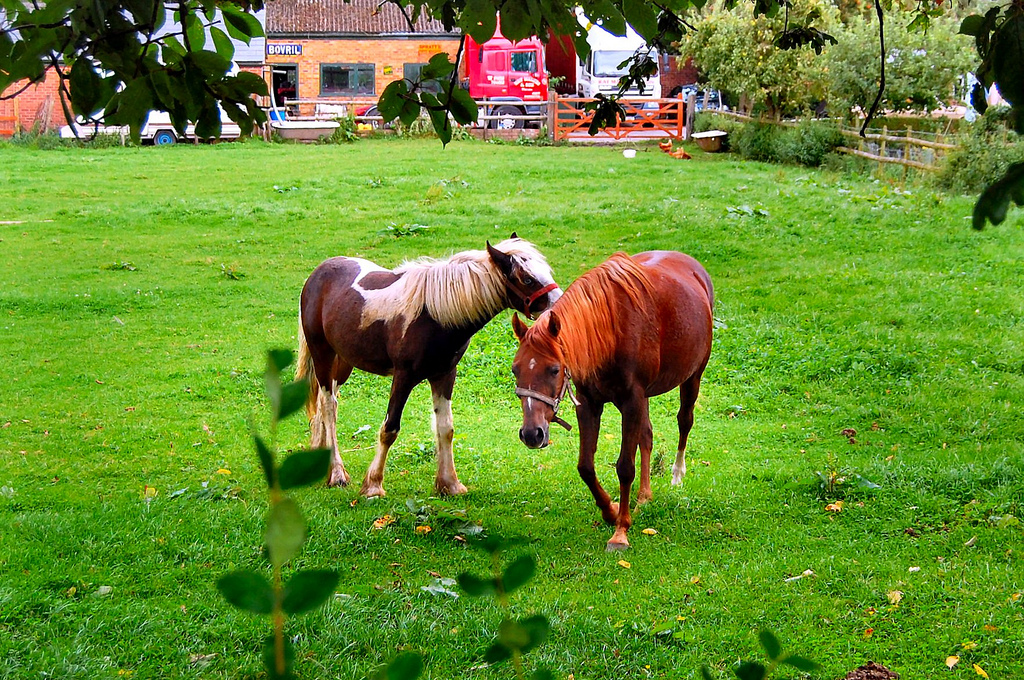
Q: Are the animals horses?
A: Yes, all the animals are horses.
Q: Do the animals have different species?
A: No, all the animals are horses.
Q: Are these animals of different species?
A: No, all the animals are horses.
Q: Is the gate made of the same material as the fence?
A: Yes, both the gate and the fence are made of wood.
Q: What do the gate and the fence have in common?
A: The material, both the gate and the fence are wooden.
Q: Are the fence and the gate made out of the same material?
A: Yes, both the fence and the gate are made of wood.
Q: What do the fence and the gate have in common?
A: The material, both the fence and the gate are wooden.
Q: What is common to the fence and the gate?
A: The material, both the fence and the gate are wooden.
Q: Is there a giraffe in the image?
A: No, there are no giraffes.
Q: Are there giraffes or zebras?
A: No, there are no giraffes or zebras.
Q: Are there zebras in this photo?
A: No, there are no zebras.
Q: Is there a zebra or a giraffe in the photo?
A: No, there are no zebras or giraffes.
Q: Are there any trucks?
A: Yes, there is a truck.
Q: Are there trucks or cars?
A: Yes, there is a truck.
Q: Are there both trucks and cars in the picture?
A: No, there is a truck but no cars.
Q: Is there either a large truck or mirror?
A: Yes, there is a large truck.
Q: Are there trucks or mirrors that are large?
A: Yes, the truck is large.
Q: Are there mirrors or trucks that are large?
A: Yes, the truck is large.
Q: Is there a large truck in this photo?
A: Yes, there is a large truck.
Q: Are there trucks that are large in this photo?
A: Yes, there is a large truck.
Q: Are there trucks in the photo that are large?
A: Yes, there is a truck that is large.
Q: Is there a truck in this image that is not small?
A: Yes, there is a large truck.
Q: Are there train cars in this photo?
A: No, there are no train cars.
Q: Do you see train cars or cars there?
A: No, there are no train cars or cars.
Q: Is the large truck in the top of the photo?
A: Yes, the truck is in the top of the image.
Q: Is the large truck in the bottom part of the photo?
A: No, the truck is in the top of the image.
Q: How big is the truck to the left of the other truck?
A: The truck is large.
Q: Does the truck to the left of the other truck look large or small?
A: The truck is large.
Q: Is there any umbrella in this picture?
A: No, there are no umbrellas.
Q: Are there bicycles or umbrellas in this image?
A: No, there are no umbrellas or bicycles.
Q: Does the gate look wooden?
A: Yes, the gate is wooden.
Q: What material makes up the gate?
A: The gate is made of wood.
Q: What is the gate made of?
A: The gate is made of wood.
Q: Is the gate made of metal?
A: No, the gate is made of wood.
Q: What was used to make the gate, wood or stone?
A: The gate is made of wood.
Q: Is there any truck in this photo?
A: Yes, there is a truck.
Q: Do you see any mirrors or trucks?
A: Yes, there is a truck.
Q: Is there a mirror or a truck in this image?
A: Yes, there is a truck.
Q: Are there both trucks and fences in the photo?
A: Yes, there are both a truck and a fence.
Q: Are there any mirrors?
A: No, there are no mirrors.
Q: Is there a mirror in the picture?
A: No, there are no mirrors.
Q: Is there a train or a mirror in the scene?
A: No, there are no mirrors or trains.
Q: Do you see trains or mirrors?
A: No, there are no mirrors or trains.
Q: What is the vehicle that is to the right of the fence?
A: The vehicle is a truck.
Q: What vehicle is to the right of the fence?
A: The vehicle is a truck.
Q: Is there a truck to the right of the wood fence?
A: Yes, there is a truck to the right of the fence.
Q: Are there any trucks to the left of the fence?
A: No, the truck is to the right of the fence.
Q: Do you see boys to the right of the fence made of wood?
A: No, there is a truck to the right of the fence.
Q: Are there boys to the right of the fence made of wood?
A: No, there is a truck to the right of the fence.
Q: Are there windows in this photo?
A: Yes, there is a window.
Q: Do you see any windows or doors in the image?
A: Yes, there is a window.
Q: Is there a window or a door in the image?
A: Yes, there is a window.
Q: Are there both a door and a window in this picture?
A: Yes, there are both a window and a door.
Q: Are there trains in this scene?
A: No, there are no trains.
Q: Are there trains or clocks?
A: No, there are no trains or clocks.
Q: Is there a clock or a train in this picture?
A: No, there are no trains or clocks.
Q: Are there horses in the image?
A: Yes, there is a horse.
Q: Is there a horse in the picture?
A: Yes, there is a horse.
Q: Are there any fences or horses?
A: Yes, there is a horse.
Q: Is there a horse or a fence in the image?
A: Yes, there is a horse.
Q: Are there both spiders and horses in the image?
A: No, there is a horse but no spiders.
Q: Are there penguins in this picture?
A: No, there are no penguins.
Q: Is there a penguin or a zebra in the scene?
A: No, there are no penguins or zebras.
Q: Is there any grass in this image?
A: Yes, there is grass.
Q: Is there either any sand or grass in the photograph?
A: Yes, there is grass.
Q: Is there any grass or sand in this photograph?
A: Yes, there is grass.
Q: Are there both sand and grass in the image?
A: No, there is grass but no sand.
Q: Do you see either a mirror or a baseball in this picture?
A: No, there are no mirrors or baseballs.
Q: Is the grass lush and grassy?
A: Yes, the grass is lush and grassy.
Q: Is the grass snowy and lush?
A: No, the grass is lush but grassy.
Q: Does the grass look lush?
A: Yes, the grass is lush.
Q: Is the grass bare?
A: No, the grass is lush.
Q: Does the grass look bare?
A: No, the grass is lush.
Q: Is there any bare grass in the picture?
A: No, there is grass but it is lush.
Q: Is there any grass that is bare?
A: No, there is grass but it is lush.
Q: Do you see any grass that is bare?
A: No, there is grass but it is lush.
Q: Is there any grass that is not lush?
A: No, there is grass but it is lush.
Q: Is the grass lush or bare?
A: The grass is lush.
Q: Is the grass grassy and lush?
A: Yes, the grass is grassy and lush.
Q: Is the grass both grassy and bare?
A: No, the grass is grassy but lush.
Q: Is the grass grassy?
A: Yes, the grass is grassy.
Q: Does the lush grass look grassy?
A: Yes, the grass is grassy.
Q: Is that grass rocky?
A: No, the grass is grassy.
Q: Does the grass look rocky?
A: No, the grass is grassy.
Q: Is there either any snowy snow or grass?
A: No, there is grass but it is grassy.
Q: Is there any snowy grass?
A: No, there is grass but it is grassy.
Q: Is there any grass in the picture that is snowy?
A: No, there is grass but it is grassy.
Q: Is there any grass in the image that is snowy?
A: No, there is grass but it is grassy.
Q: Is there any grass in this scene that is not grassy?
A: No, there is grass but it is grassy.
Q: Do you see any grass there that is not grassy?
A: No, there is grass but it is grassy.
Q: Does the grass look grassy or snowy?
A: The grass is grassy.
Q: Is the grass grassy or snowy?
A: The grass is grassy.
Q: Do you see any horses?
A: Yes, there is a horse.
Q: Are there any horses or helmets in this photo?
A: Yes, there is a horse.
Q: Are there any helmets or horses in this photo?
A: Yes, there is a horse.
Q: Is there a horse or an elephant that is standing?
A: Yes, the horse is standing.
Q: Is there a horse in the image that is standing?
A: Yes, there is a horse that is standing.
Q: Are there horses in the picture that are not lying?
A: Yes, there is a horse that is standing.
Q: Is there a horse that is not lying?
A: Yes, there is a horse that is standing.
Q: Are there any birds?
A: No, there are no birds.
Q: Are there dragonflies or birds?
A: No, there are no birds or dragonflies.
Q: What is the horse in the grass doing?
A: The horse is standing.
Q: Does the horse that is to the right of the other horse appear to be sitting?
A: No, the horse is standing.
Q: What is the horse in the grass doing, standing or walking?
A: The horse is standing.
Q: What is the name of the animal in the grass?
A: The animal is a horse.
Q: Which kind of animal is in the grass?
A: The animal is a horse.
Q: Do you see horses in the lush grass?
A: Yes, there is a horse in the grass.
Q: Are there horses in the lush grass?
A: Yes, there is a horse in the grass.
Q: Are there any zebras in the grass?
A: No, there is a horse in the grass.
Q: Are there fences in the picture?
A: Yes, there is a fence.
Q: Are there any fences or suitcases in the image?
A: Yes, there is a fence.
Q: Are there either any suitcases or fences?
A: Yes, there is a fence.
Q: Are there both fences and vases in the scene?
A: No, there is a fence but no vases.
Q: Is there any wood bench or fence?
A: Yes, there is a wood fence.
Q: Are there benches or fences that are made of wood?
A: Yes, the fence is made of wood.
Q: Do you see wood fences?
A: Yes, there is a wood fence.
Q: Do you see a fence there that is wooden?
A: Yes, there is a fence that is wooden.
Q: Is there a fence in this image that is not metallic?
A: Yes, there is a wooden fence.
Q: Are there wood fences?
A: Yes, there is a fence that is made of wood.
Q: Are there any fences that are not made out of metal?
A: Yes, there is a fence that is made of wood.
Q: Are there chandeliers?
A: No, there are no chandeliers.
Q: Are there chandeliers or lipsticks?
A: No, there are no chandeliers or lipsticks.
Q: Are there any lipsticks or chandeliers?
A: No, there are no chandeliers or lipsticks.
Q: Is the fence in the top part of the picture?
A: Yes, the fence is in the top of the image.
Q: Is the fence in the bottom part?
A: No, the fence is in the top of the image.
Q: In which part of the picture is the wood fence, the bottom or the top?
A: The fence is in the top of the image.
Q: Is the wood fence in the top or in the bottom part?
A: The fence is in the top of the image.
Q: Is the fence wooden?
A: Yes, the fence is wooden.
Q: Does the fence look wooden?
A: Yes, the fence is wooden.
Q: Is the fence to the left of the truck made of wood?
A: Yes, the fence is made of wood.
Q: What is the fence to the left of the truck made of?
A: The fence is made of wood.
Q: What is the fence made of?
A: The fence is made of wood.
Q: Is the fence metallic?
A: No, the fence is wooden.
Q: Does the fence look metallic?
A: No, the fence is wooden.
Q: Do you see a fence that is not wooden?
A: No, there is a fence but it is wooden.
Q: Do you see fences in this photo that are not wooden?
A: No, there is a fence but it is wooden.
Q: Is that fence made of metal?
A: No, the fence is made of wood.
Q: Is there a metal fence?
A: No, there is a fence but it is made of wood.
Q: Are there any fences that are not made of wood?
A: No, there is a fence but it is made of wood.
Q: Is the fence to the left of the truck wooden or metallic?
A: The fence is wooden.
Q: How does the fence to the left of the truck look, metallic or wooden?
A: The fence is wooden.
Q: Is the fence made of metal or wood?
A: The fence is made of wood.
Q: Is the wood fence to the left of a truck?
A: Yes, the fence is to the left of a truck.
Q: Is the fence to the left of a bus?
A: No, the fence is to the left of a truck.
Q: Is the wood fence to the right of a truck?
A: No, the fence is to the left of a truck.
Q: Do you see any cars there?
A: No, there are no cars.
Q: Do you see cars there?
A: No, there are no cars.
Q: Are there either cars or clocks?
A: No, there are no cars or clocks.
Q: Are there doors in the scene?
A: Yes, there is a door.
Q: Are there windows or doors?
A: Yes, there is a door.